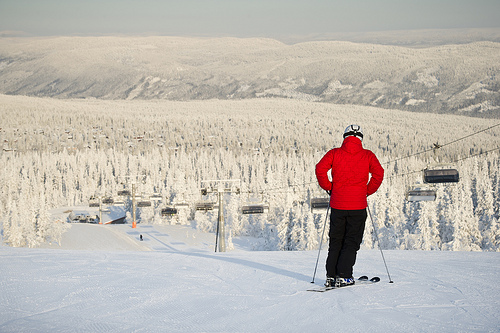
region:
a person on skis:
[283, 118, 383, 281]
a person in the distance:
[122, 224, 189, 266]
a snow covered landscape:
[50, 102, 267, 287]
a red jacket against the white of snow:
[310, 135, 409, 225]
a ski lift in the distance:
[184, 177, 264, 260]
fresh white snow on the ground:
[76, 257, 218, 313]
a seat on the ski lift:
[420, 160, 472, 193]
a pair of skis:
[297, 263, 404, 298]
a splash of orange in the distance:
[116, 217, 157, 230]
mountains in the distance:
[62, 37, 418, 132]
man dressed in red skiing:
[292, 95, 423, 308]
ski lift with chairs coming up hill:
[104, 174, 306, 221]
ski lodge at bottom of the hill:
[64, 199, 132, 227]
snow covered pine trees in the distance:
[23, 100, 248, 175]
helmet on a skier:
[339, 120, 369, 138]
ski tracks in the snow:
[72, 257, 195, 319]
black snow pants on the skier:
[332, 205, 364, 287]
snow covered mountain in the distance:
[30, 33, 475, 98]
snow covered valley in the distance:
[39, 66, 362, 112]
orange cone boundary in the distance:
[129, 220, 141, 230]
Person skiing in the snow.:
[304, 123, 396, 298]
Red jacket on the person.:
[312, 119, 383, 294]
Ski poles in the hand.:
[305, 183, 340, 289]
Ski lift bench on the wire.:
[422, 164, 460, 184]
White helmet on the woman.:
[339, 121, 364, 148]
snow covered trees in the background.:
[0, 92, 498, 251]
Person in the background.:
[135, 231, 148, 243]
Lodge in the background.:
[66, 200, 131, 227]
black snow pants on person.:
[312, 122, 384, 287]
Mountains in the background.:
[1, 32, 498, 118]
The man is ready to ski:
[310, 123, 381, 284]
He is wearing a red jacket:
[331, 147, 376, 194]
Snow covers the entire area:
[49, 70, 464, 282]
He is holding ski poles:
[308, 185, 390, 282]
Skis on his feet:
[303, 267, 389, 328]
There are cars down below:
[52, 190, 288, 241]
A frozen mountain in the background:
[19, 38, 492, 107]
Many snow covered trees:
[24, 102, 301, 224]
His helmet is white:
[340, 118, 369, 134]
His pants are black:
[325, 213, 366, 285]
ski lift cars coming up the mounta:
[90, 168, 497, 215]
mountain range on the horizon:
[6, 39, 491, 113]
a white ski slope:
[13, 222, 488, 332]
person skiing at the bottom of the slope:
[137, 234, 142, 241]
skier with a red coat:
[309, 123, 396, 290]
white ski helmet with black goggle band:
[342, 125, 364, 140]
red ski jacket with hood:
[317, 139, 386, 204]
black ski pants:
[327, 210, 366, 275]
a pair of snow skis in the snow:
[306, 275, 381, 297]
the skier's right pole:
[367, 202, 397, 282]